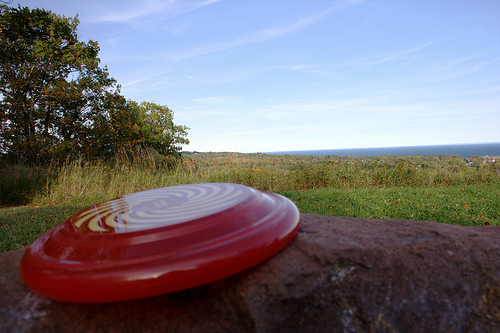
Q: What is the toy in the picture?
A: Frisbee.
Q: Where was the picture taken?
A: Beach.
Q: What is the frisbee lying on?
A: Rock.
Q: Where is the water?
A: In the back.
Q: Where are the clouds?
A: Sky.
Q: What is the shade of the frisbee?
A: Red.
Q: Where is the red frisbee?
A: On a stone.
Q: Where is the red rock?
A: In a field.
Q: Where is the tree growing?
A: In the field.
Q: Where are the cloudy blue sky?
A: Over the ocean.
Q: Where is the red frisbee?
A: Sitting on the rock.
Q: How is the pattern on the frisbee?
A: Yellow.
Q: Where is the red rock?
A: Sitting on the ground.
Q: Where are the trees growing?
A: On a hill.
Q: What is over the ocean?
A: Partly cloudy blue sky.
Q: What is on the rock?
A: A red frisbee.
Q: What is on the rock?
A: A frisbee.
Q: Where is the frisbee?
A: On a rock.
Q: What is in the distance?
A: The ocean.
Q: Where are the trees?
A: Behind the tall grass.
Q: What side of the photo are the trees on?
A: Left side.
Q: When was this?
A: Daytime.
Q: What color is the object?
A: Red.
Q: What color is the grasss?
A: Green.